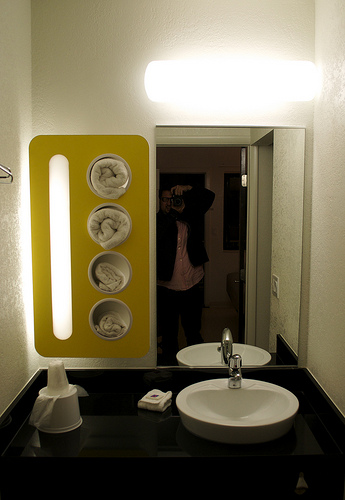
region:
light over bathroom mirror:
[140, 57, 328, 109]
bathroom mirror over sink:
[152, 121, 308, 372]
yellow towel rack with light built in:
[27, 130, 152, 364]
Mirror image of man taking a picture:
[156, 182, 221, 366]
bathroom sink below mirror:
[173, 351, 301, 447]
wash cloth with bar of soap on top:
[134, 384, 173, 413]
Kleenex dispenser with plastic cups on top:
[33, 382, 86, 435]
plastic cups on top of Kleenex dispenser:
[43, 359, 73, 396]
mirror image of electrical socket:
[268, 270, 280, 302]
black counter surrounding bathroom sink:
[0, 364, 344, 498]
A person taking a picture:
[38, 82, 297, 495]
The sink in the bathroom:
[169, 350, 301, 447]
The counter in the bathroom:
[89, 421, 186, 467]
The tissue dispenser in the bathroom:
[32, 359, 92, 440]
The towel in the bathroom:
[137, 381, 177, 416]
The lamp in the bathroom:
[39, 151, 76, 342]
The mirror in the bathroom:
[148, 118, 311, 376]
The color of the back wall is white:
[21, 2, 134, 104]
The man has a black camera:
[169, 185, 192, 213]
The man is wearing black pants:
[155, 282, 208, 366]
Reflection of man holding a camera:
[159, 183, 185, 211]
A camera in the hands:
[172, 194, 182, 206]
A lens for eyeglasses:
[162, 197, 167, 201]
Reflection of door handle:
[233, 278, 239, 282]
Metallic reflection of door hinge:
[242, 175, 245, 184]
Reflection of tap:
[223, 332, 233, 352]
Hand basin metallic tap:
[234, 355, 240, 386]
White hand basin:
[209, 389, 274, 420]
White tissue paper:
[38, 400, 48, 414]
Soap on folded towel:
[152, 394, 157, 397]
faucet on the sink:
[209, 346, 251, 388]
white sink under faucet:
[209, 383, 278, 435]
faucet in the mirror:
[203, 328, 238, 360]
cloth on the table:
[137, 380, 180, 416]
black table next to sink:
[122, 416, 167, 447]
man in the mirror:
[151, 178, 217, 233]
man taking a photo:
[147, 169, 225, 239]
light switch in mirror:
[262, 269, 289, 299]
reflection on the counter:
[115, 422, 165, 458]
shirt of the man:
[160, 223, 201, 276]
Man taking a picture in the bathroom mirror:
[155, 183, 217, 345]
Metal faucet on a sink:
[228, 353, 239, 386]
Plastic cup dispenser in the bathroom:
[30, 353, 82, 431]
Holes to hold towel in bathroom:
[80, 151, 129, 333]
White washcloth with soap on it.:
[134, 385, 168, 407]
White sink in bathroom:
[176, 352, 304, 438]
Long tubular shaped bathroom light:
[49, 153, 72, 342]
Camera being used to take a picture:
[171, 189, 184, 208]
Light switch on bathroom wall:
[269, 270, 279, 298]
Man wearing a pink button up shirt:
[156, 182, 216, 341]